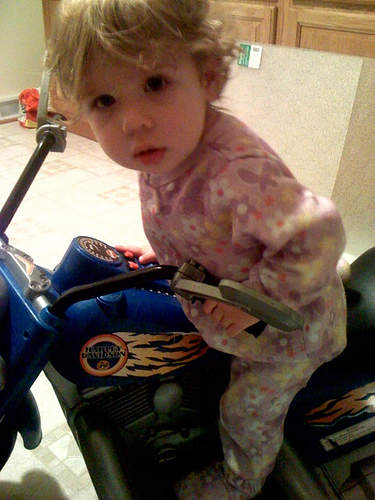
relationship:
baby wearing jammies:
[42, 2, 349, 499] [138, 108, 353, 497]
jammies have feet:
[138, 108, 353, 497] [178, 465, 257, 498]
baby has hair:
[42, 2, 349, 499] [15, 9, 279, 96]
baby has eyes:
[42, 2, 349, 499] [84, 66, 170, 110]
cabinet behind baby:
[42, 1, 372, 58] [42, 2, 349, 499]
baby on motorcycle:
[48, 2, 349, 496] [1, 110, 374, 495]